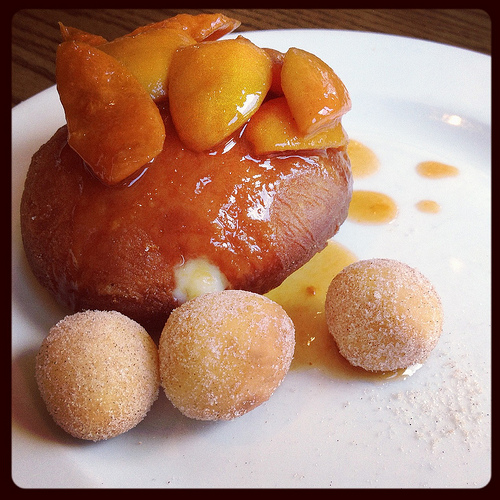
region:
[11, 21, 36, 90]
this is a table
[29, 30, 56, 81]
the table is brown in color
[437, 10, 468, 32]
the table is wooden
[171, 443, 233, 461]
this is a plate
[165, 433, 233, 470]
the plate is white in color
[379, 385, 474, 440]
this is some sprinkle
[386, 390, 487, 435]
the sprinkles are white in color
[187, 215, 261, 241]
this is a doughnut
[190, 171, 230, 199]
the doughnut is oily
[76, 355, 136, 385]
the doughnuts have sprinkles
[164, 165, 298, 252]
this is a doughnut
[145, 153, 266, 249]
the doughnut is creamy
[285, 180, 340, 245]
the doughnut is brown in color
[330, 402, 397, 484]
this is a plate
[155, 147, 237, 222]
the cream is yummy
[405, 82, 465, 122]
the plate is white in color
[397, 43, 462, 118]
the plate is round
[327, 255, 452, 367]
this is a fruit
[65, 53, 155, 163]
this is a food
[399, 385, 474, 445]
the floor are on the plate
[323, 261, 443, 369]
one round ball covered in sugar to the far right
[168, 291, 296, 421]
one round ball covered in sugar in the middle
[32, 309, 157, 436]
one round ball covered in sugar to the far left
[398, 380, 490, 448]
sugar crystals on the plate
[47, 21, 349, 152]
golden slices of something drench in yellow syrup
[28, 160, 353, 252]
appears to be a potato with skin still on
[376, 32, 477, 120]
white plate for holding the food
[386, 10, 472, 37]
wooden table for the plate to sit on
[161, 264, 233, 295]
a white custard on the potato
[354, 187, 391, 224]
the sauce is dripping on the plate now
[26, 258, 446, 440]
three ball shaped food on a plate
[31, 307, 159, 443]
food is covered in sugar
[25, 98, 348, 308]
a big dessert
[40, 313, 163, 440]
food is light yellow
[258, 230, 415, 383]
light brown syrup on the plate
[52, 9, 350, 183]
soaked peaches on the plate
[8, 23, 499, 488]
plate is a white color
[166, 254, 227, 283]
white cream inside the pastry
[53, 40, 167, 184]
peach is a yellow color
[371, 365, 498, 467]
sugar on the plate